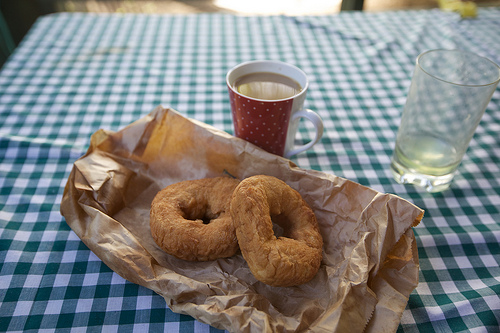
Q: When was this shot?
A: Daytime.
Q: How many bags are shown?
A: 1.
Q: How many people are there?
A: 0.